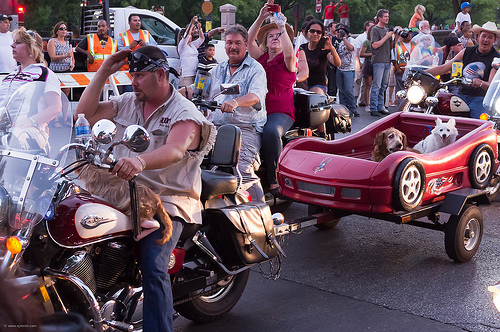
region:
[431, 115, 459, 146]
the head of a dog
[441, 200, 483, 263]
a black and white wheel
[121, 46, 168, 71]
a pair of sunglasses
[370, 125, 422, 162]
a brown dog in the car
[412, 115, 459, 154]
a white dog in the car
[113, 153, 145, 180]
the hand of a man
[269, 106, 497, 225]
a small red dog car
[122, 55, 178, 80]
a black and white bandanna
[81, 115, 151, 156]
two side view mirrors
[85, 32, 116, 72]
an orange vest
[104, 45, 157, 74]
a hand grasping sunglasses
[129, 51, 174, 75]
a bandana tied around a head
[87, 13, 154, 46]
men wearing orange safety vests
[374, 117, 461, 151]
dogs riding in a toy car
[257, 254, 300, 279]
a chain hanging on the connector bar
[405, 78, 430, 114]
a headlight shining on a motorcycle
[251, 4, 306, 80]
a woman taking a selfie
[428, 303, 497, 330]
cracks in the pavement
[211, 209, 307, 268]
a leather bag on a motorcycle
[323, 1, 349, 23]
two men wearing red shirts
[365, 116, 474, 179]
dogs riding in car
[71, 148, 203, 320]
dog sitting on motorcycle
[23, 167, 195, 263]
red motorcycle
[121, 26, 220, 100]
man has bandana on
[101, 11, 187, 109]
man has sunglasses on his head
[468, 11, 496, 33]
man has cowboy hat on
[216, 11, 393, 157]
woman riding on back of motorcycle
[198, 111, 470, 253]
car being pulled by motorcycle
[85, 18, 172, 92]
men have reflector vests on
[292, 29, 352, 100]
woman has a black shirt on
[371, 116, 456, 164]
Two dogs riding in a small red car.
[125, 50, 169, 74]
Dark sunglasses on a mans head.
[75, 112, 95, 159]
Plastic bottle of water on a motorcycle.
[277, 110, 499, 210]
Small red car with two dogs inside.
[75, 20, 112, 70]
colored man standing with orange safety vest on.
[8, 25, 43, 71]
Head of a blonde woman.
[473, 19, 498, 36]
Cowboy hat on a man.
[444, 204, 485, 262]
Wheel on the front of a small trailer.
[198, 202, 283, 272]
Black saddlebag on a motorcycle.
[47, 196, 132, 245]
Gas tank of a motorcycle.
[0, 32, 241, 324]
man on motorcycle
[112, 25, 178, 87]
man holding sun glasses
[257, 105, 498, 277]
red car with dogs sitting inside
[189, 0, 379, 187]
man and lady on motorcycle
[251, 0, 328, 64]
lady taking picture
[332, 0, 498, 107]
people standing and watching the motorcycles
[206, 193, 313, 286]
black bag on side of motorcycle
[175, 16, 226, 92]
lady taking pictures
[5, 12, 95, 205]
lady sitting on motorcycle